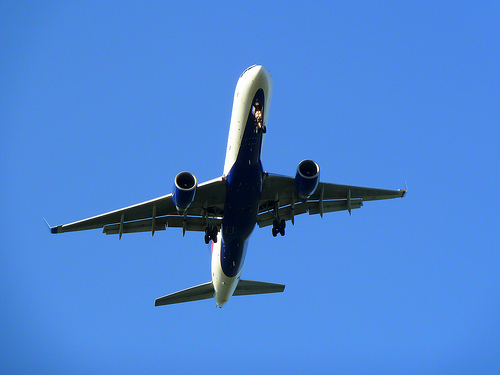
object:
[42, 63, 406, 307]
plane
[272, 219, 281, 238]
wheels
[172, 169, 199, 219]
engines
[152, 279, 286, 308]
tail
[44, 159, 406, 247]
wings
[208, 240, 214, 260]
stripe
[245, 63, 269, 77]
nose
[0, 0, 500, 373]
sky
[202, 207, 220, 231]
gear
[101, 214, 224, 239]
flaps